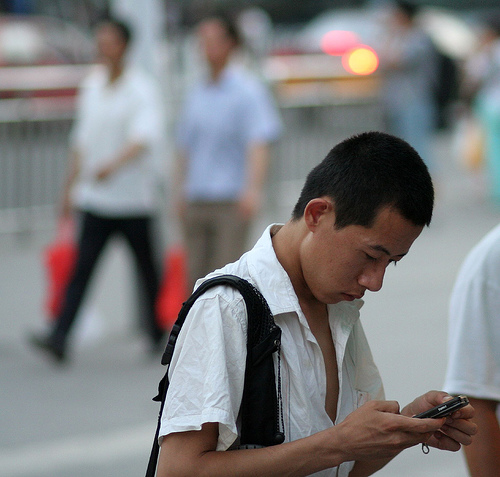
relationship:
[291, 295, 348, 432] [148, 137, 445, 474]
chest of a man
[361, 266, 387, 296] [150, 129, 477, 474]
nose on person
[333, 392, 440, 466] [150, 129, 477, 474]
hand on person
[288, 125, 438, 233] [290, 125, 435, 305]
black hair on head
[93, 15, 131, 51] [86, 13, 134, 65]
black hair on head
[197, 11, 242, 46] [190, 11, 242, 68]
black hair on head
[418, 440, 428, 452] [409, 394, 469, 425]
strap on cellphone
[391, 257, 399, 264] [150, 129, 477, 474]
lashes on person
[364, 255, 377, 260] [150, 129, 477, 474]
lashes on person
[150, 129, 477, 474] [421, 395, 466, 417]
person looking at phone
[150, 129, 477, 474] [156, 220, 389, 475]
person wearing shirt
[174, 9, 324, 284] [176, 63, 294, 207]
person wearing shirt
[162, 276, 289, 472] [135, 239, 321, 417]
bag on shoulder